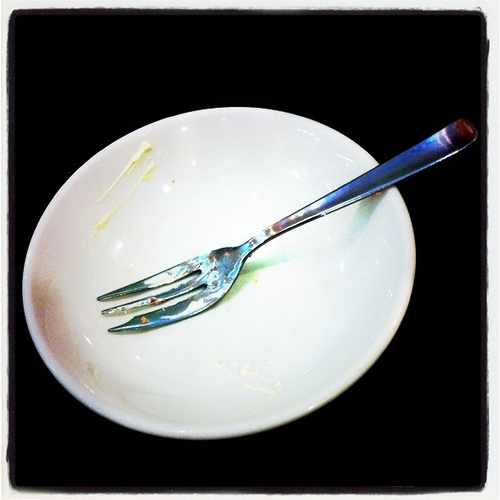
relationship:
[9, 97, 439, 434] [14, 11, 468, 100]
plate on table cloth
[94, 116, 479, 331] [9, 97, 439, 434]
fork on plate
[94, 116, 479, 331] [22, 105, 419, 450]
fork on plate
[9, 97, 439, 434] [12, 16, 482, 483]
plate kept on table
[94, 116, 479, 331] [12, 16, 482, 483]
fork kept on table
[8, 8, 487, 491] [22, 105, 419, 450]
table cloth with plate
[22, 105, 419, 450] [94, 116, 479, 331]
plate and fork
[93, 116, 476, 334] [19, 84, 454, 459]
fork on plate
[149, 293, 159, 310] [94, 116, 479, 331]
food residue still on fork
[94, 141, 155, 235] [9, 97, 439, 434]
cream on a plate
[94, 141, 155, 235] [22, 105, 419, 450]
cream on a plate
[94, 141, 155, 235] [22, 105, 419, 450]
cream on plate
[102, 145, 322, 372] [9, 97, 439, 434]
light reflection on plate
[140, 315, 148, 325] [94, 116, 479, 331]
crumbs on fork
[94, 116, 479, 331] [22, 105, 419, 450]
fork in a plate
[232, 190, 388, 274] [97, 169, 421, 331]
shadow of fork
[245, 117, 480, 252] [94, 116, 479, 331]
handle of fork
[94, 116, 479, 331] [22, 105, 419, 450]
fork with plate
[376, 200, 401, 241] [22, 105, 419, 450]
frosting on a plate